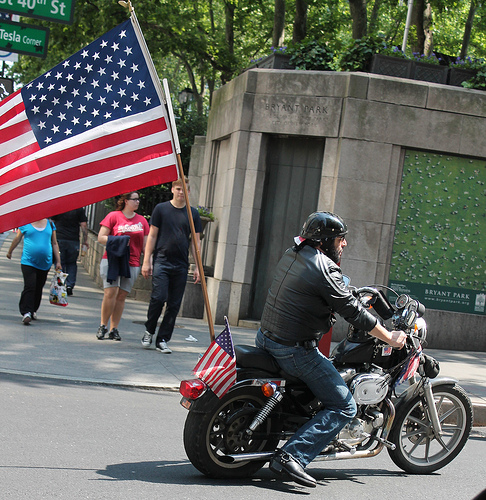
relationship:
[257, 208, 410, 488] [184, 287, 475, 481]
man riding motorcycle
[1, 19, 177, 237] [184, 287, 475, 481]
flag on motorcycle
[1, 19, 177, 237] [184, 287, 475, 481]
flag in motorcycle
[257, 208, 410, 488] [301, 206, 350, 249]
man wearing helmet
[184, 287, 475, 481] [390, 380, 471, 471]
motorcycle has wheel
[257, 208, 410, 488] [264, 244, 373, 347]
man wearing shirt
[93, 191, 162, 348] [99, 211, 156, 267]
woman wearing shirt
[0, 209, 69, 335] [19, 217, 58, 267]
person wearing shirt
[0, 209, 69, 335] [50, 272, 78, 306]
person holding bag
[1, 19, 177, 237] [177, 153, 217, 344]
flag on pole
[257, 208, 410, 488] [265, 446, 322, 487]
man wearing boot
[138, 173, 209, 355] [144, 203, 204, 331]
man in black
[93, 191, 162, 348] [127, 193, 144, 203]
woman wearing glasses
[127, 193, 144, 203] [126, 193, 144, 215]
glasses are on face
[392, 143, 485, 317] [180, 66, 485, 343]
picture on wall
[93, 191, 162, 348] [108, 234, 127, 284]
woman carrying jacket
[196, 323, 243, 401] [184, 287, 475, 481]
flag on motorcycle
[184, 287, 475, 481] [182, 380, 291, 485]
motorcycle has wheel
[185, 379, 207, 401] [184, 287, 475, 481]
light in motorcycle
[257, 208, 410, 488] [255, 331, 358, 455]
man wearing jeans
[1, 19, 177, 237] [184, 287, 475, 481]
flag tied to motorcycle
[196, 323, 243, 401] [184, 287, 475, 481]
flag tied to motorcycle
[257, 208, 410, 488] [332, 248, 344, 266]
man has beard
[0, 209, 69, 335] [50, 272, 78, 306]
person carrying bag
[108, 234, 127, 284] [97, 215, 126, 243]
jacket on arm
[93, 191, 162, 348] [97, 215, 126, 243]
woman has arm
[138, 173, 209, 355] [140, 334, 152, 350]
man wearing shoe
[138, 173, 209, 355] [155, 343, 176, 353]
man wearing shoe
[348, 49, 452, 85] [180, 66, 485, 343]
boxes are on top of wall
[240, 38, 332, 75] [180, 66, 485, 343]
boxes are on top of wall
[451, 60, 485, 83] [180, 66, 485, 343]
boxes are on top of wall